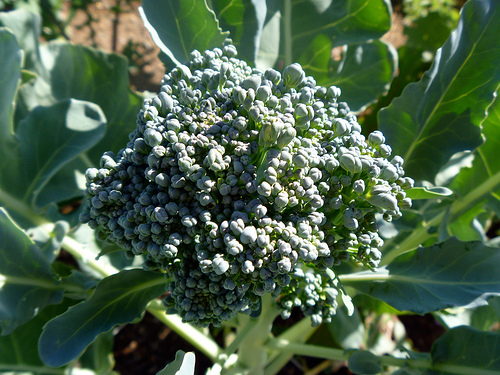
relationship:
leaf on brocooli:
[373, 7, 498, 179] [53, 22, 478, 339]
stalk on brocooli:
[230, 293, 279, 374] [53, 22, 478, 339]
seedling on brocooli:
[332, 111, 346, 126] [53, 22, 478, 339]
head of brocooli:
[75, 44, 414, 322] [53, 22, 478, 339]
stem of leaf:
[337, 266, 382, 286] [343, 230, 497, 322]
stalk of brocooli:
[230, 293, 279, 374] [53, 22, 478, 339]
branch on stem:
[421, 258, 459, 281] [337, 266, 382, 286]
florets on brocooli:
[148, 131, 201, 179] [53, 22, 478, 339]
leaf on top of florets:
[373, 7, 498, 179] [148, 131, 201, 179]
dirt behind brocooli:
[112, 329, 169, 373] [53, 22, 478, 339]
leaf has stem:
[343, 230, 497, 322] [337, 266, 382, 286]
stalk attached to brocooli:
[230, 293, 279, 374] [53, 22, 478, 339]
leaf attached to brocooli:
[373, 7, 498, 179] [53, 22, 478, 339]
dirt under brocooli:
[112, 329, 169, 373] [53, 22, 478, 339]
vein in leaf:
[395, 114, 468, 152] [373, 7, 498, 179]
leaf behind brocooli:
[373, 7, 498, 179] [53, 22, 478, 339]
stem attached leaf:
[337, 266, 382, 286] [373, 7, 498, 179]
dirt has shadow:
[112, 329, 169, 373] [124, 63, 160, 88]